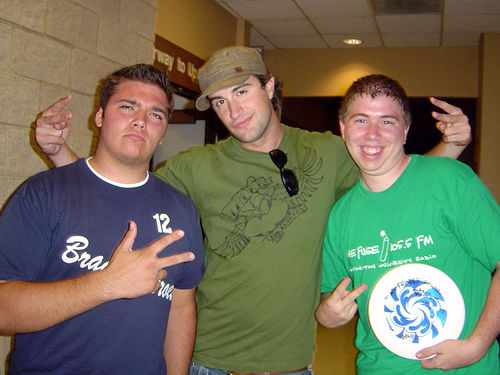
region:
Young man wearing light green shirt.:
[315, 35, 495, 370]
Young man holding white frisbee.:
[305, 66, 494, 373]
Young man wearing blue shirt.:
[2, 53, 211, 374]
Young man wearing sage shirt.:
[157, 40, 346, 374]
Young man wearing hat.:
[178, 29, 341, 230]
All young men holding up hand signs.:
[28, 50, 478, 304]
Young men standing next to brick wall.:
[3, 5, 419, 276]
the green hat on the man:
[195, 45, 268, 111]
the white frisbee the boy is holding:
[367, 262, 465, 360]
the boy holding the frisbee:
[313, 71, 499, 372]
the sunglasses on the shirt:
[268, 146, 300, 196]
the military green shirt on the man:
[153, 122, 360, 371]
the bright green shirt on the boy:
[321, 153, 498, 373]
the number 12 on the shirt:
[152, 212, 172, 234]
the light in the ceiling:
[343, 35, 362, 45]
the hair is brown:
[98, 64, 173, 127]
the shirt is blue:
[0, 157, 203, 372]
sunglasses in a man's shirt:
[267, 143, 302, 205]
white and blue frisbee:
[366, 255, 466, 364]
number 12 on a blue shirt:
[151, 210, 173, 239]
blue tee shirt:
[3, 149, 210, 374]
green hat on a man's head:
[192, 39, 266, 116]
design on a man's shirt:
[208, 138, 322, 265]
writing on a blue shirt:
[58, 230, 174, 303]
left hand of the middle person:
[422, 90, 476, 162]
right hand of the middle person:
[27, 92, 82, 167]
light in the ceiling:
[341, 33, 363, 50]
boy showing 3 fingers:
[94, 218, 226, 326]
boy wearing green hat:
[182, 40, 299, 160]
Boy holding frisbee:
[358, 264, 489, 370]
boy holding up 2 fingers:
[428, 93, 483, 156]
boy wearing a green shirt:
[161, 115, 354, 367]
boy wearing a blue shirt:
[10, 160, 233, 373]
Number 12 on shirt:
[141, 201, 174, 242]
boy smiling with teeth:
[344, 139, 401, 166]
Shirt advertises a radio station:
[336, 228, 456, 273]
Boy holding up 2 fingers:
[281, 253, 401, 350]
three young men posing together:
[2, 45, 499, 374]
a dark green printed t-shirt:
[150, 122, 364, 369]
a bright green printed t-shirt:
[320, 154, 498, 374]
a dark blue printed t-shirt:
[0, 156, 203, 373]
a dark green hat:
[193, 45, 268, 109]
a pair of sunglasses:
[269, 148, 299, 195]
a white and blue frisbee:
[367, 264, 463, 359]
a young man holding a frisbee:
[317, 71, 499, 368]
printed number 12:
[152, 210, 171, 236]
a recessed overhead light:
[341, 36, 360, 46]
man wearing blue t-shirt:
[11, 40, 203, 356]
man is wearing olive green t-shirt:
[140, 19, 319, 360]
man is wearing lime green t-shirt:
[311, 60, 496, 367]